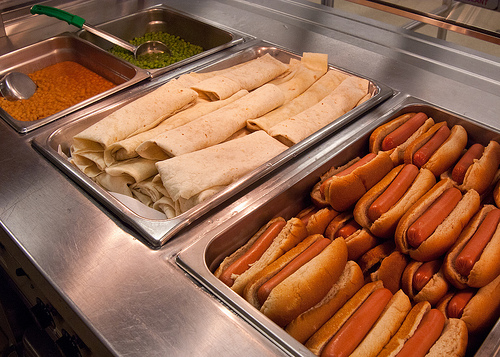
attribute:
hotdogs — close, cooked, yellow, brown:
[202, 115, 500, 351]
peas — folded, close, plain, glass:
[83, 10, 222, 67]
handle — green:
[29, 1, 88, 28]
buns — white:
[215, 106, 497, 355]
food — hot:
[70, 50, 377, 219]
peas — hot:
[104, 27, 206, 70]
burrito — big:
[155, 128, 289, 201]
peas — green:
[111, 30, 204, 70]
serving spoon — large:
[28, 3, 172, 61]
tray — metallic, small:
[1, 30, 151, 135]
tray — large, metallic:
[178, 95, 498, 355]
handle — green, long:
[27, 3, 86, 27]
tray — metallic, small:
[76, 1, 244, 81]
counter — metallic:
[0, 0, 497, 354]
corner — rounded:
[135, 214, 180, 247]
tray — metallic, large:
[31, 40, 395, 248]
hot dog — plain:
[396, 306, 444, 355]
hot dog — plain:
[322, 286, 392, 355]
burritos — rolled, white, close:
[68, 50, 377, 220]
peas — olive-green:
[103, 30, 208, 72]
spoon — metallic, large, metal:
[29, 4, 172, 62]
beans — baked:
[2, 59, 122, 120]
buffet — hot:
[1, 0, 499, 353]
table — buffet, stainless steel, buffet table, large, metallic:
[1, 1, 461, 352]